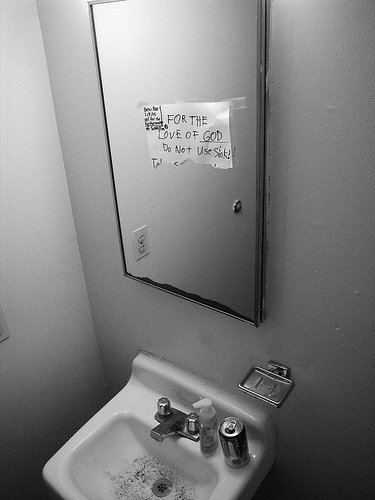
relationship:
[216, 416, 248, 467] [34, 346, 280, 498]
can on sink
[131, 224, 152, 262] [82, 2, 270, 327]
socket reflected in mirror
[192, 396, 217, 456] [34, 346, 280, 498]
soap on sink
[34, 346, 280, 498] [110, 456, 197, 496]
sink has debris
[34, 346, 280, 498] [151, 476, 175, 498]
sink has a drain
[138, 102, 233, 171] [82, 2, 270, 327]
note on mirror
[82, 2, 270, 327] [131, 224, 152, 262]
mirror reflects outlet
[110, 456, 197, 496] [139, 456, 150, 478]
filth in sink black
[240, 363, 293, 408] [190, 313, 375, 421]
dish attached to wall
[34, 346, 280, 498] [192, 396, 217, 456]
sink dispenses soap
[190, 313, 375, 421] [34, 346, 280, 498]
wall attached to sink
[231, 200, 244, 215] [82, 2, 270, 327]
stopper reflected in mirror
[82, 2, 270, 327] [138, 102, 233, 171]
mirror has a sign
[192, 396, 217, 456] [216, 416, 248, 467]
bottle next to can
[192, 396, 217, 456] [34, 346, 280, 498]
bottle on sink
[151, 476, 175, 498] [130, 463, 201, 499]
hole at bottom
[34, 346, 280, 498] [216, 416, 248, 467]
sink has a can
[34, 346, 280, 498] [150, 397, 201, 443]
sink has a faucet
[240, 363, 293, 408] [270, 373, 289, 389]
soap dish made of metal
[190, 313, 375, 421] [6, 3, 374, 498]
wall in bathroom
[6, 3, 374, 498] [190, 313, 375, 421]
bathroom has a wall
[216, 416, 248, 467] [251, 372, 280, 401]
can next to soap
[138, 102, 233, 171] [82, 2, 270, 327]
paper taped to mirror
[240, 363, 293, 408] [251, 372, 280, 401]
dish for soap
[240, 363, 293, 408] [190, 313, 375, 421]
dish hanging on wall